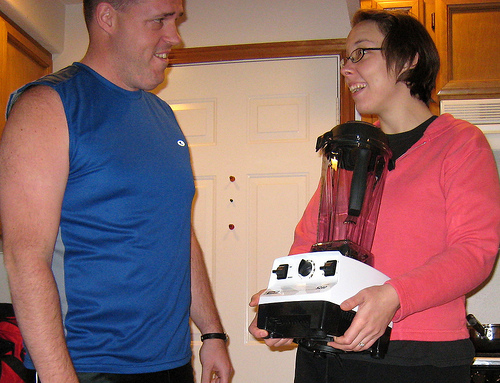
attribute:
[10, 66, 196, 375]
shirt — blue, grey, tank top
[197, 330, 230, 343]
watch — black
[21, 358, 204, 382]
pants — black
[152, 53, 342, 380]
door — white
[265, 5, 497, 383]
woman — smiling, happy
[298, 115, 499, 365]
sweater — red, pink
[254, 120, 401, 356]
blender — electric, black, white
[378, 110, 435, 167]
shirt — black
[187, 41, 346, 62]
frame — wooden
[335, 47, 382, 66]
glasses — black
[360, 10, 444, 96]
hair — brown, short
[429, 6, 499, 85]
cabinets — wood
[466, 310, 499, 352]
pot — black, silver, saucepan